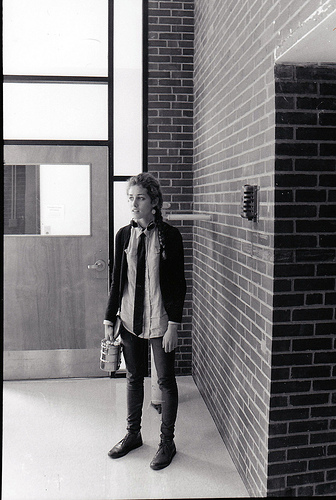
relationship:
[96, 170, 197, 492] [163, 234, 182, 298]
girl wearing jacket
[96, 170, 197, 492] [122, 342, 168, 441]
girl wearing jeans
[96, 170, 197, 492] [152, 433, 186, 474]
girl has boot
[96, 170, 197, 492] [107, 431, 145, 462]
girl has boot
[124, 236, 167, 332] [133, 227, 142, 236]
shirt has collar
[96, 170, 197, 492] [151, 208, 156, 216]
girl has earring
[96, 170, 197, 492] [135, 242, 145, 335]
girl wearing tie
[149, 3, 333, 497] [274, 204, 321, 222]
wall has brick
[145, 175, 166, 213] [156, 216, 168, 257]
hair has braid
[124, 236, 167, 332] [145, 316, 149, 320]
shirt has button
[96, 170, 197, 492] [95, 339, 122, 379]
girl holding object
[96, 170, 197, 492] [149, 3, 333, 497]
girl near wall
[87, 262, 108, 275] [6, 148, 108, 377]
handle on door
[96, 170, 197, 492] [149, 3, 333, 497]
girl next to wall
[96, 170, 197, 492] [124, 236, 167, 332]
girl has shirt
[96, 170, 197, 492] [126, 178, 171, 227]
girl has head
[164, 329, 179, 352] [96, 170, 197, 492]
hand of girl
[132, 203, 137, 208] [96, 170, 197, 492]
nose of girl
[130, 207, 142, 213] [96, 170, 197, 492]
mouth of girl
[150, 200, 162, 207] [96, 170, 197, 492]
ear of girl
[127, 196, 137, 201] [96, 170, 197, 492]
eye of girl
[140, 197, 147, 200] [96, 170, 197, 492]
eye of girl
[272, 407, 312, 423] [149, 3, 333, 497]
brick in wall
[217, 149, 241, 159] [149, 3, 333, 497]
brick in wall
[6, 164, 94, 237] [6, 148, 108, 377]
window in door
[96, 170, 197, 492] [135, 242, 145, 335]
girl has tie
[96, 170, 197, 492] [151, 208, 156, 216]
girl wearing earring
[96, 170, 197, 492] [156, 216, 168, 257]
girl has braid